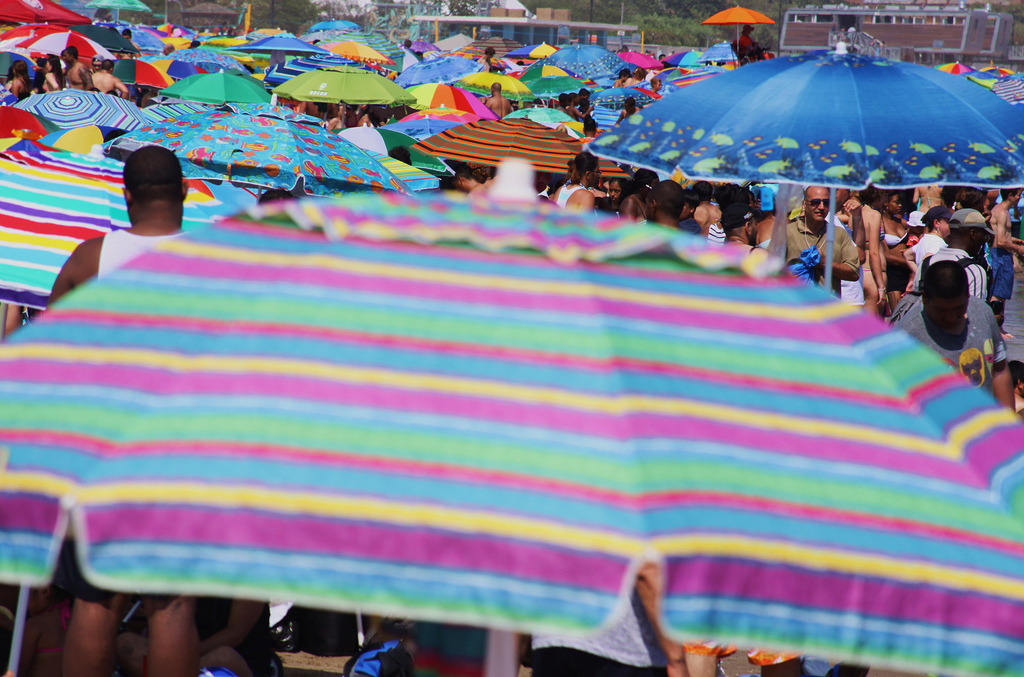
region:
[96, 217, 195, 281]
Man is wearing a shirt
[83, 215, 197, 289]
Man wearing a white shirt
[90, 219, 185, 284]
Man is wearing a white shirt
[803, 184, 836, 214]
Man is wearing sunglasses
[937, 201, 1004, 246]
Man wearing a hat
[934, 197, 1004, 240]
Man is wearing a hat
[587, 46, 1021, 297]
Dark blue umbrella with light green fish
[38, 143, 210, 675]
Black man in white shirt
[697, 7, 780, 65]
Lifeguard sitting in tower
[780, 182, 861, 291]
White man holding blue object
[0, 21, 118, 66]
two red and white pinwheel umbrellas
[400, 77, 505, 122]
Rainbow colored umbrella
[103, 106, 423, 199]
umbrella with multi-colored fish pattern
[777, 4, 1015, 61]
wooden buildings with many windows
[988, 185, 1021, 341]
boy wearing blue swim trunks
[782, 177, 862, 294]
man wearing sun glasses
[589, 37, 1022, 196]
blue umbrella with green fish on it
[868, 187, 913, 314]
woman wearing white bikini top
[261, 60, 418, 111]
lime green umbrella with white logo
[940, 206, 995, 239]
grey and tan ball cap on man's head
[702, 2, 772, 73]
orange umbrella above crowd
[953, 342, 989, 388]
Luchadore face on man's t-shirt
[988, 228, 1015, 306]
denim board shorts on young man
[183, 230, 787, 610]
an umbrella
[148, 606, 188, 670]
a persons leg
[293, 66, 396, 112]
a green umbrella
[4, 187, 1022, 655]
large colorful umbrella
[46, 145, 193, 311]
man in a white shirt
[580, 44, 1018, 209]
large blue umbrella with green fish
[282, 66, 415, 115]
a large green umbrella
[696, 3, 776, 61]
a large orange umbrella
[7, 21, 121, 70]
a large red and white umbrella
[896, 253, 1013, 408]
man in a grey t-shirt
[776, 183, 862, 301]
man wearing sunglasses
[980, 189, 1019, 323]
man with no shirt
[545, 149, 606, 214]
man in a white muscle shirt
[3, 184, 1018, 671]
a colorful striped beach umbrella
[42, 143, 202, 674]
man behind the umbrella facing away